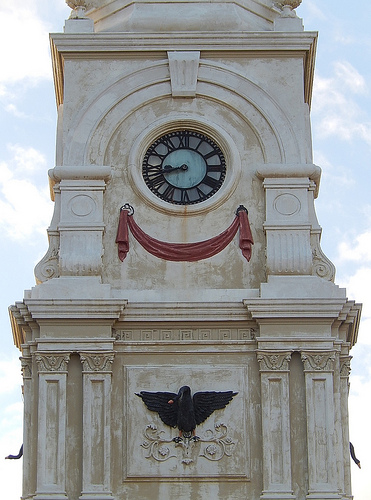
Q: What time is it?
A: 8:43.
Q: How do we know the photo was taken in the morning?
A: It is 8:43 and it is light outside.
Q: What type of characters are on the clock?
A: Roman numerals.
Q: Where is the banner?
A: Beneath the clock.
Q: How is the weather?
A: Partly cloudy.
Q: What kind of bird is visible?
A: Black swan.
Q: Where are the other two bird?
A: On the sides of the clock.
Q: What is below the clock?
A: Sash.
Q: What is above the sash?
A: Clock.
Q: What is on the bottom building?
A: Bird.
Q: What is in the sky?
A: Clouds.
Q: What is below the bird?
A: Flowers.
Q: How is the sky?
A: Partly cloudy.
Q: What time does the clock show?
A: 8:44.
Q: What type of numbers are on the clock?
A: Roman numerals.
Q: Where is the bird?
A: On tower.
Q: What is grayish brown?
A: Tower.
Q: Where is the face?
A: On clock.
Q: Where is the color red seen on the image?
A: Representation of draped cloth.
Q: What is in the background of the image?
A: Sky.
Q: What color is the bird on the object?
A: Black.